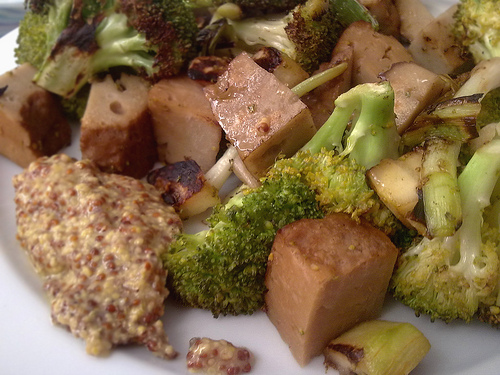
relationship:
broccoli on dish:
[159, 132, 376, 323] [0, 0, 500, 372]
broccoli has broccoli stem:
[17, 0, 202, 104] [343, 82, 399, 166]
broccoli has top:
[17, 0, 202, 104] [12, 0, 198, 100]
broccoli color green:
[14, 17, 178, 72] [100, 27, 135, 62]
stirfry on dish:
[5, 1, 499, 373] [0, 0, 500, 372]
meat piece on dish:
[263, 217, 395, 361] [0, 0, 500, 372]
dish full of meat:
[68, 86, 435, 300] [79, 67, 159, 177]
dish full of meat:
[68, 86, 435, 300] [263, 205, 395, 361]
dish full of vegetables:
[68, 86, 435, 300] [391, 130, 497, 322]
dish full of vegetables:
[68, 86, 435, 300] [265, 85, 405, 240]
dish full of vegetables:
[68, 86, 435, 300] [160, 162, 324, 321]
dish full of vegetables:
[68, 86, 435, 300] [17, 0, 214, 108]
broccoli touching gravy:
[169, 84, 409, 317] [1, 18, 497, 373]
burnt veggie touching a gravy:
[150, 157, 213, 206] [7, 51, 499, 371]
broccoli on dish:
[284, 81, 402, 236] [0, 0, 500, 372]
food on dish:
[16, 25, 484, 373] [0, 0, 500, 372]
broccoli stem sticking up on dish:
[459, 136, 499, 226] [0, 0, 500, 372]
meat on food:
[198, 50, 323, 172] [0, 2, 499, 373]